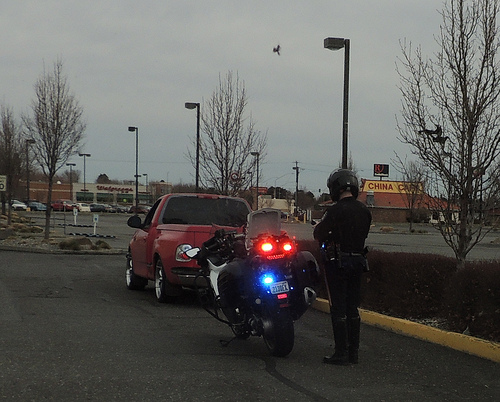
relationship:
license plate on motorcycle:
[270, 280, 290, 295] [187, 208, 321, 356]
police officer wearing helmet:
[312, 170, 370, 362] [325, 165, 360, 203]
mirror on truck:
[127, 213, 142, 230] [123, 193, 254, 308]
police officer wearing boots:
[312, 170, 370, 362] [324, 315, 362, 366]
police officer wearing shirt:
[312, 170, 370, 362] [314, 198, 372, 254]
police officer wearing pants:
[312, 170, 370, 362] [322, 255, 367, 316]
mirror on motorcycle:
[185, 248, 202, 258] [187, 208, 321, 356]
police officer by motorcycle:
[312, 170, 370, 362] [187, 208, 321, 356]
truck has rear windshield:
[123, 193, 254, 308] [163, 196, 249, 228]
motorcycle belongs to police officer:
[187, 208, 321, 356] [312, 170, 370, 362]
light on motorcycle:
[262, 243, 272, 255] [187, 208, 321, 356]